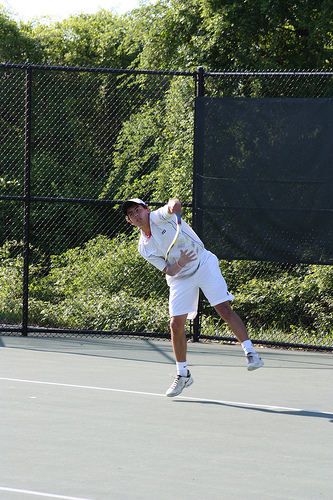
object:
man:
[122, 191, 265, 398]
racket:
[166, 208, 201, 279]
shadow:
[171, 398, 331, 418]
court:
[1, 324, 330, 497]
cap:
[123, 197, 151, 207]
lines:
[0, 375, 330, 419]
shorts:
[165, 249, 233, 318]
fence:
[2, 64, 331, 353]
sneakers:
[165, 347, 264, 398]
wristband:
[176, 259, 184, 270]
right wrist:
[172, 261, 182, 270]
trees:
[3, 1, 328, 333]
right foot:
[166, 368, 194, 398]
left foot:
[246, 349, 265, 372]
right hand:
[178, 249, 198, 263]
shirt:
[137, 205, 209, 278]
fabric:
[198, 99, 332, 261]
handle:
[176, 208, 181, 226]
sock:
[175, 360, 189, 376]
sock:
[241, 339, 256, 355]